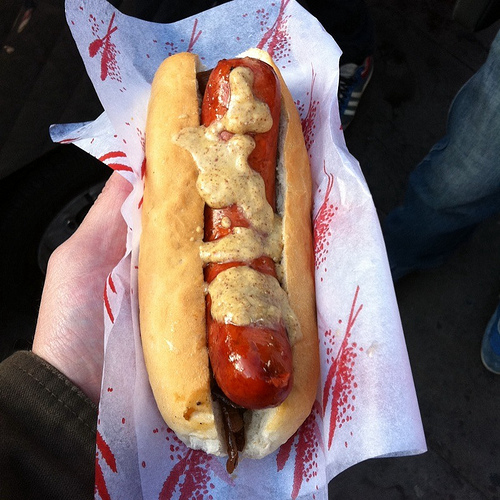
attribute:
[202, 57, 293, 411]
hotdog — here, red, cooked, brown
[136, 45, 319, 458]
bun — brown, toasted, long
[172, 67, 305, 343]
mustard — brown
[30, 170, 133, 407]
hand — white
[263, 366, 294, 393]
tip — tied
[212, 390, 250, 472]
onion — caramelized, salted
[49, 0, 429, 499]
paper — colored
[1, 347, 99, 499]
sleeve — brown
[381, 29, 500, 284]
jeans — blue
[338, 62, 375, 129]
shoe — striped